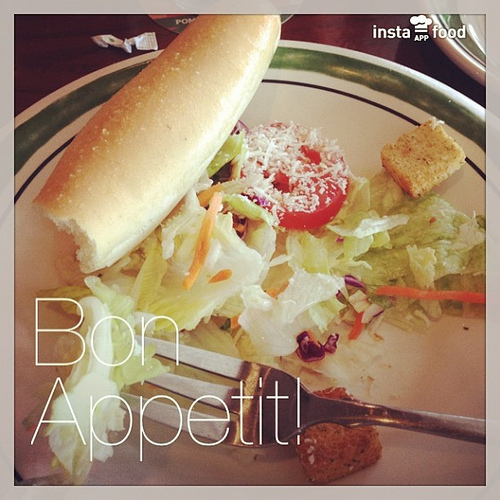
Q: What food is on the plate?
A: Salad.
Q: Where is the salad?
A: Next to bread.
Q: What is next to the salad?
A: Fork.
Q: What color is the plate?
A: White.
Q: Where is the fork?
A: Plate.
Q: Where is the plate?
A: Table.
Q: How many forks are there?
A: One.